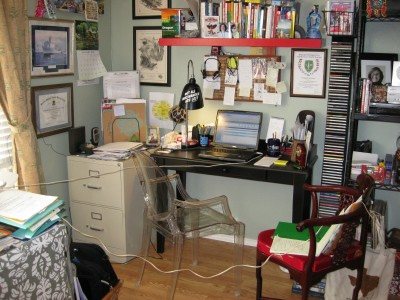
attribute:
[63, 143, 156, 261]
file cabinet — two drawer, beige, white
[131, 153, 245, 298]
chair — see-through, plastic, brown, clear, wooden, dark brown, dark wood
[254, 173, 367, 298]
chair — wooden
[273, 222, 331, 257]
notebooks — piled, green, white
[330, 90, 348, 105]
cd — stacked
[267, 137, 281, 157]
cup — black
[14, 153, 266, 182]
wire — strung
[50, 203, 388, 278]
wire — strung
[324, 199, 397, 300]
bag — white, beige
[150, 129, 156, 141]
photo — framed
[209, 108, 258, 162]
laptop — open, silver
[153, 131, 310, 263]
desk — black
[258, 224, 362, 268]
seat — red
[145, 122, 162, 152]
frame — wood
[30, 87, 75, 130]
diploma — framed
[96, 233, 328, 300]
floor — hardwood, brown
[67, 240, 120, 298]
backpack — black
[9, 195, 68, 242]
folders — stacked, white, blue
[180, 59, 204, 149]
lamp — black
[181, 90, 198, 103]
letters — white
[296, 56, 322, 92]
certificate — framed